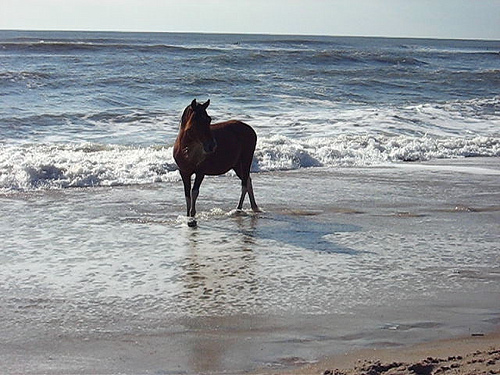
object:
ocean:
[0, 29, 499, 285]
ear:
[199, 99, 210, 113]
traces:
[248, 329, 500, 374]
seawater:
[0, 28, 499, 346]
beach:
[0, 208, 499, 374]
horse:
[163, 93, 273, 218]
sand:
[243, 322, 499, 375]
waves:
[0, 98, 499, 189]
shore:
[0, 160, 499, 374]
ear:
[190, 96, 197, 113]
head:
[179, 98, 209, 136]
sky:
[0, 0, 499, 43]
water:
[0, 32, 499, 358]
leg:
[228, 169, 263, 211]